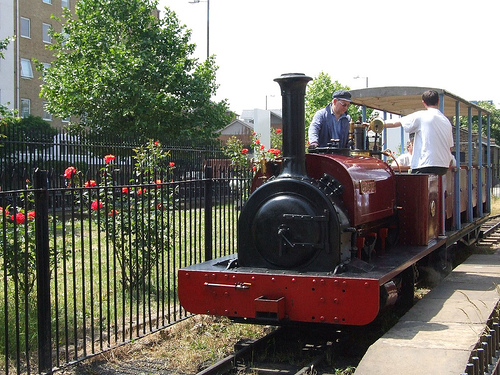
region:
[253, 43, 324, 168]
A smoke stack on a train.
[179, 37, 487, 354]
A little red and black train.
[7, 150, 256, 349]
A black fence next to a train.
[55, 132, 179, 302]
A rose bush next to a fence.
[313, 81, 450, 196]
Two people are at the front of the train.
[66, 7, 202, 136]
A green tree in the distance.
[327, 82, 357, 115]
The man is wearing a hat.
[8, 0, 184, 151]
A tall building in the distance.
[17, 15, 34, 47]
A window on a building.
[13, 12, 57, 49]
Two windows next to each other.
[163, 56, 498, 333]
Train runs on rails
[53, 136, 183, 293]
Red flowers behind a fence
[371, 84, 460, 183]
Man wearing white shirt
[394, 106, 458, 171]
Shirt is color white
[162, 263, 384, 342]
Train bumper is red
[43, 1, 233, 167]
Big tree on a park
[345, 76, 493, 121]
Roof of train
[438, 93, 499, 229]
Sticks supporting the roof are gray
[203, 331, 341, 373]
Rails of train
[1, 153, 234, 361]
Fence of garden is black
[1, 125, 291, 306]
red rose bushes are behind the fence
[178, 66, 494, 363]
a train is on a small gauge track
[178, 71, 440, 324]
the engine is black and red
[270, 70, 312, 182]
the smoke stack is black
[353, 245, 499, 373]
a platform for the train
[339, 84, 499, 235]
the train pulls an open air seating car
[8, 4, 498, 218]
buildings are behind the train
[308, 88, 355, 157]
the train engineer is wearing a gray cap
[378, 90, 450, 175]
a man with a white shirt is facing the passengers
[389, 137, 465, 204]
poeple are in the passenger car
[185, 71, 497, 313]
Amusement park train ride.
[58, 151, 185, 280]
Beautiful red rose bush.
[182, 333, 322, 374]
Railroad tracks.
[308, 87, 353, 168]
Train conductor with blue hat.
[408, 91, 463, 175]
Tour guide wearing white shirt.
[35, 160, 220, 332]
Wrought Iron Fence.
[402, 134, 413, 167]
Passenger on train ride.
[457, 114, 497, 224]
Seating on amusement park train ride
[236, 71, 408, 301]
Replica steam engine.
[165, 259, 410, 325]
Front grill of train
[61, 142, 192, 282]
a bush with red roses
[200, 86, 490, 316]
a red open train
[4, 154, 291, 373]
a black iron fence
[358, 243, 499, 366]
a ramp next to a train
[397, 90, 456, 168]
a white shirt on a man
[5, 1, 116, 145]
a tall brick building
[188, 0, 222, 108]
a tall street light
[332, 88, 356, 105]
a cap on a man's head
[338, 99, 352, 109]
sunglasses on a man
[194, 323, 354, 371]
tracks under a train